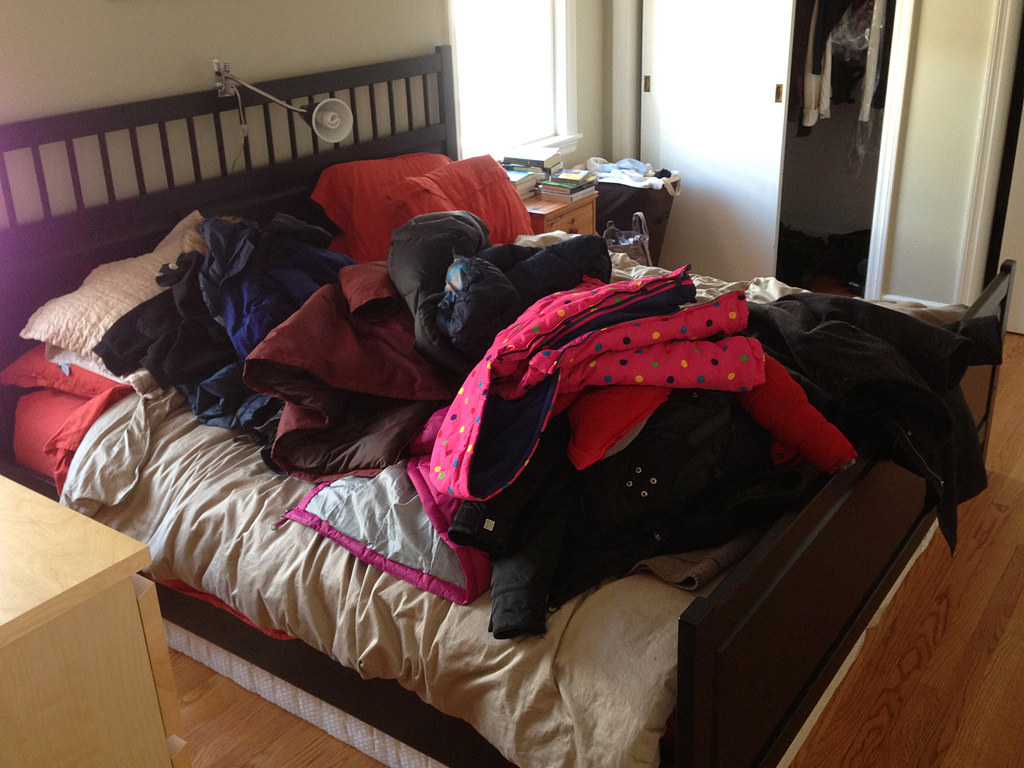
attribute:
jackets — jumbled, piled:
[88, 203, 994, 579]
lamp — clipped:
[201, 41, 360, 161]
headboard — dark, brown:
[4, 35, 455, 299]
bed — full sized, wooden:
[7, 27, 1014, 754]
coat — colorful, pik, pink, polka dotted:
[416, 255, 781, 508]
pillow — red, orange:
[349, 142, 546, 268]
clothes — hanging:
[792, 8, 913, 135]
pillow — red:
[0, 340, 137, 403]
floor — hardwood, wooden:
[165, 272, 1024, 766]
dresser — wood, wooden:
[3, 472, 189, 766]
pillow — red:
[316, 132, 458, 252]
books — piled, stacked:
[538, 161, 599, 211]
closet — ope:
[607, 6, 991, 317]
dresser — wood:
[520, 167, 602, 235]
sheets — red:
[18, 395, 94, 475]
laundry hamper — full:
[558, 150, 682, 259]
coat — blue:
[190, 206, 358, 359]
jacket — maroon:
[236, 245, 461, 476]